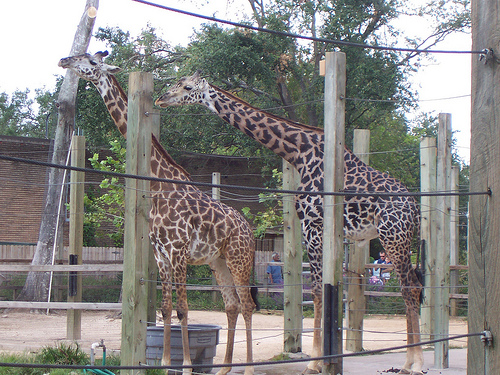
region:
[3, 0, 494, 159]
the sunny sky above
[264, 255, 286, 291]
a man in blue standing by a building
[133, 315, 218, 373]
a trash can sitting by a giraffe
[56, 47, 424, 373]
two giraffes standing in the zoo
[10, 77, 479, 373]
a fence surrounding the giraffes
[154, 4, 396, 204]
a big leafy tree behind the giraffes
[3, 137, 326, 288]
the building in the background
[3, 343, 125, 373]
the grass on the ground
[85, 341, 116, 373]
the garden hose attached to the faucet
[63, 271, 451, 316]
some more bushes by the fence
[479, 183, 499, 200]
small hole in wood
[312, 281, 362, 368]
black bottom of large post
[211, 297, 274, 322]
wide knees of giraffe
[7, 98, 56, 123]
cluster of green trees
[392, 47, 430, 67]
long branch on tree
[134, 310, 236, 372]
large gray water holder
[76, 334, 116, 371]
green and silver pipes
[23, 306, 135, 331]
clear sand on ground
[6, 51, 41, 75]
clear skies overhead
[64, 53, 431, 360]
large pair of giraffes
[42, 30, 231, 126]
Two giraffes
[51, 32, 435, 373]
Two giraffes standing next to each other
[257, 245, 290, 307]
Man standing in distance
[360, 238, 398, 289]
Man with child in his arms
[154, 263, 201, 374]
Front two legs of giraffe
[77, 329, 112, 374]
Water faucet and hose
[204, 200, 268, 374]
Back half of giraffe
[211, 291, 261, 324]
Knees on back legs of giraffe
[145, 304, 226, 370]
Plastic container near a giraffe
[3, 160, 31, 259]
Side of brick building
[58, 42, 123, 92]
A giraffe looking up.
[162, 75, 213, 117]
A giraffe looking down.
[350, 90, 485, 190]
Ropes of a fence.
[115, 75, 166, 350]
Poles of a fence.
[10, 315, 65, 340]
Brown dirt where the giraffes are.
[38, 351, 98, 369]
Green grass around the giraffes.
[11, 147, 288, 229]
Brick building next to the giraffes.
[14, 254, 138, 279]
Wooden fence for the giraffes.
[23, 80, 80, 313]
Tree trunk around the giraffes.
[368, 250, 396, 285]
People looking at the giraffes.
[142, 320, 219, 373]
Gray water bucket near giraffes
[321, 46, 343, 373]
Fencepost on giraffe cage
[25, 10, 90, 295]
Tall gray dead tree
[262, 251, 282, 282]
Man in blue shirt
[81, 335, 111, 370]
Green garden hose on grass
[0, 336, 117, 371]
Patch of green grass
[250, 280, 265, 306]
Black tufted end of tail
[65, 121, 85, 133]
Metal rods on top of post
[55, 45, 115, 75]
Raised spotted giraffe head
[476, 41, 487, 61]
Metal fence connector